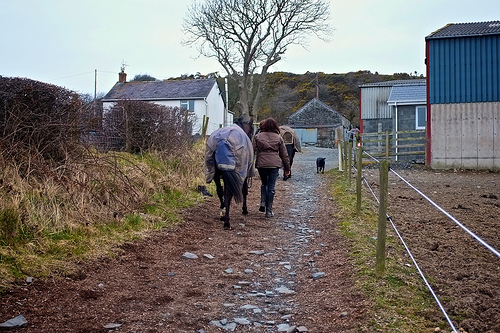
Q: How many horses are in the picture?
A: Two.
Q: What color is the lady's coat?
A: Brown.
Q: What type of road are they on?
A: Dirt Road.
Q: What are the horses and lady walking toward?
A: The buildings.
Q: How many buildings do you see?
A: Five.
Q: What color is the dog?
A: Black.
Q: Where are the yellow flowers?
A: On the Mountains.